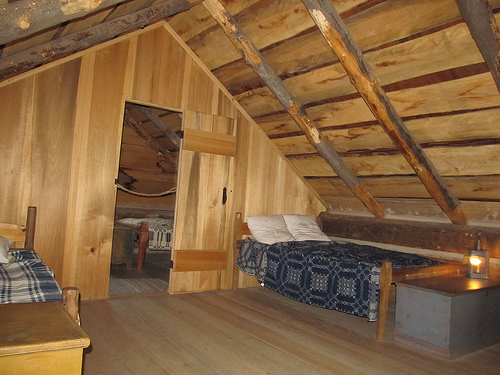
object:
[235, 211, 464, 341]
bed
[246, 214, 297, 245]
pillow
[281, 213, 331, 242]
pillow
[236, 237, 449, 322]
blanket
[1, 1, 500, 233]
roof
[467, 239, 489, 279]
light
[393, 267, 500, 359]
table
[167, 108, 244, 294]
door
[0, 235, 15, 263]
pillow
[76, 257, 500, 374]
floor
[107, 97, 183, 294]
bedroom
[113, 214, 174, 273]
bed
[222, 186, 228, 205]
handle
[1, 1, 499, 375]
cabin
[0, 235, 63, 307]
bed